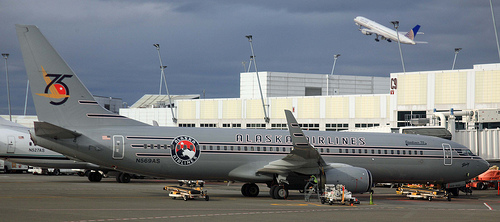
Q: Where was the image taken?
A: It was taken at the airport.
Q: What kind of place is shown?
A: It is an airport.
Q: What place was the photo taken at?
A: It was taken at the airport.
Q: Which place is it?
A: It is an airport.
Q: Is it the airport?
A: Yes, it is the airport.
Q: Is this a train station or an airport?
A: It is an airport.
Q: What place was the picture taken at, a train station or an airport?
A: It was taken at an airport.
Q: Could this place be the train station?
A: No, it is the airport.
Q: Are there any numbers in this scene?
A: Yes, there are numbers.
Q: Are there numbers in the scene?
A: Yes, there are numbers.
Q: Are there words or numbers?
A: Yes, there are numbers.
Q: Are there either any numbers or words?
A: Yes, there are numbers.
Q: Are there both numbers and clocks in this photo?
A: No, there are numbers but no clocks.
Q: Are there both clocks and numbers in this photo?
A: No, there are numbers but no clocks.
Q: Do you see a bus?
A: No, there are no buses.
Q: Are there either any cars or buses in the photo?
A: No, there are no buses or cars.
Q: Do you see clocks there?
A: No, there are no clocks.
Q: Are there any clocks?
A: No, there are no clocks.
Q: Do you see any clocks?
A: No, there are no clocks.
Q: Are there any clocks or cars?
A: No, there are no clocks or cars.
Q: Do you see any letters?
A: Yes, there are letters.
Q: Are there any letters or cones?
A: Yes, there are letters.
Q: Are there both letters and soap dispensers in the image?
A: No, there are letters but no soap dispensers.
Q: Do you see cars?
A: No, there are no cars.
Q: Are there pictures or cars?
A: No, there are no cars or pictures.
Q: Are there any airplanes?
A: Yes, there is an airplane.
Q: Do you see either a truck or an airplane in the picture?
A: Yes, there is an airplane.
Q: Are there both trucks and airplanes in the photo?
A: No, there is an airplane but no trucks.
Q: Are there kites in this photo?
A: No, there are no kites.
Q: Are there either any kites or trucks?
A: No, there are no kites or trucks.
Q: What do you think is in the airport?
A: The airplane is in the airport.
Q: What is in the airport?
A: The airplane is in the airport.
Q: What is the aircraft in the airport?
A: The aircraft is an airplane.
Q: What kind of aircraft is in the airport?
A: The aircraft is an airplane.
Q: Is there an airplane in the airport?
A: Yes, there is an airplane in the airport.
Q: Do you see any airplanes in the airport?
A: Yes, there is an airplane in the airport.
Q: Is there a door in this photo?
A: Yes, there is a door.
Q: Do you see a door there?
A: Yes, there is a door.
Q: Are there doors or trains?
A: Yes, there is a door.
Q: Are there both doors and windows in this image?
A: Yes, there are both a door and a window.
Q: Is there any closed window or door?
A: Yes, there is a closed door.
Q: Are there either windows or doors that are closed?
A: Yes, the door is closed.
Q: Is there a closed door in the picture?
A: Yes, there is a closed door.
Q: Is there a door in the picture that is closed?
A: Yes, there is a door that is closed.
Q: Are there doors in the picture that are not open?
A: Yes, there is an closed door.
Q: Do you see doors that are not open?
A: Yes, there is an closed door.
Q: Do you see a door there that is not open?
A: Yes, there is an closed door.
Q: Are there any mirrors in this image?
A: No, there are no mirrors.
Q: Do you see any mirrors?
A: No, there are no mirrors.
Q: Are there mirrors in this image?
A: No, there are no mirrors.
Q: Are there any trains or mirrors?
A: No, there are no mirrors or trains.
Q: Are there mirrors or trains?
A: No, there are no mirrors or trains.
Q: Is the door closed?
A: Yes, the door is closed.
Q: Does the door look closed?
A: Yes, the door is closed.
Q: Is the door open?
A: No, the door is closed.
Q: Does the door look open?
A: No, the door is closed.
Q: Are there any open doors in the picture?
A: No, there is a door but it is closed.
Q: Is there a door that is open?
A: No, there is a door but it is closed.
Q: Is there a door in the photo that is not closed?
A: No, there is a door but it is closed.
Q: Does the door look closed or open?
A: The door is closed.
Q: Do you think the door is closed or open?
A: The door is closed.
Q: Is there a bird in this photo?
A: No, there are no birds.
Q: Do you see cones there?
A: No, there are no cones.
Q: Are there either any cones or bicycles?
A: No, there are no cones or bicycles.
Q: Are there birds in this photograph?
A: No, there are no birds.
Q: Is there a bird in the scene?
A: No, there are no birds.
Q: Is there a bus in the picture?
A: No, there are no buses.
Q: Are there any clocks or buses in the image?
A: No, there are no buses or clocks.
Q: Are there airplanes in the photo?
A: Yes, there is an airplane.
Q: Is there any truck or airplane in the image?
A: Yes, there is an airplane.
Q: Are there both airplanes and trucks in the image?
A: No, there is an airplane but no trucks.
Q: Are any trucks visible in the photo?
A: No, there are no trucks.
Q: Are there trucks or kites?
A: No, there are no trucks or kites.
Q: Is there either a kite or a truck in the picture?
A: No, there are no trucks or kites.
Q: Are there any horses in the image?
A: No, there are no horses.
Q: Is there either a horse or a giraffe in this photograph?
A: No, there are no horses or giraffes.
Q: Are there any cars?
A: No, there are no cars.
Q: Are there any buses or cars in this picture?
A: No, there are no cars or buses.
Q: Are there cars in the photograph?
A: No, there are no cars.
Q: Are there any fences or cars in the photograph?
A: No, there are no cars or fences.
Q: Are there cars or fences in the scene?
A: No, there are no cars or fences.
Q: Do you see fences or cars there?
A: No, there are no cars or fences.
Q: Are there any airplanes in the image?
A: Yes, there is an airplane.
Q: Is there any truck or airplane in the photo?
A: Yes, there is an airplane.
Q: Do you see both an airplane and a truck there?
A: No, there is an airplane but no trucks.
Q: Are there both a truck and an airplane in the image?
A: No, there is an airplane but no trucks.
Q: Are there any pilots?
A: No, there are no pilots.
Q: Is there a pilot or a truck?
A: No, there are no pilots or trucks.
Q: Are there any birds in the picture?
A: No, there are no birds.